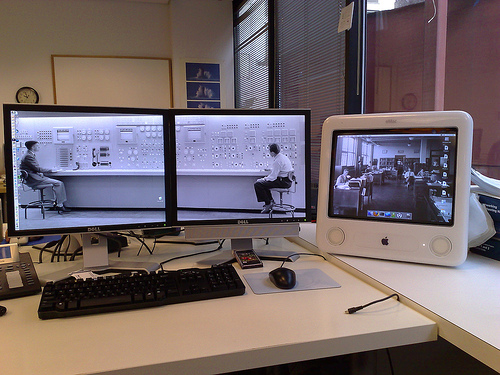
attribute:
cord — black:
[345, 290, 403, 318]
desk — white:
[1, 234, 500, 372]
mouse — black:
[270, 269, 294, 288]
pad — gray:
[244, 267, 338, 292]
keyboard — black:
[38, 266, 241, 316]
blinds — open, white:
[273, 0, 346, 127]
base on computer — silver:
[81, 232, 109, 273]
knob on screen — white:
[326, 226, 348, 248]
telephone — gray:
[2, 243, 40, 300]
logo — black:
[381, 233, 391, 249]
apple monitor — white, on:
[316, 121, 482, 262]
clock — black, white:
[17, 89, 39, 101]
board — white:
[52, 57, 173, 107]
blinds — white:
[235, 7, 275, 109]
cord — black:
[282, 249, 325, 266]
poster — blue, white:
[186, 63, 219, 108]